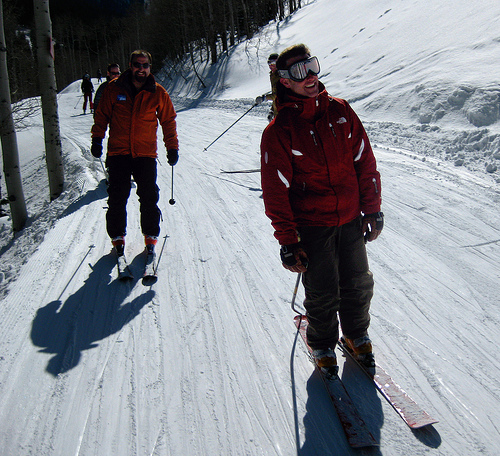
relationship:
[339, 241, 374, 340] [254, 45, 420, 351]
leg of person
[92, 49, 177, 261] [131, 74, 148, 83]
man with goatee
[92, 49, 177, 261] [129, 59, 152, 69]
man with sunglasses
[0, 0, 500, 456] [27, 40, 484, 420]
ground covering ground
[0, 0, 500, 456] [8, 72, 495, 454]
ground covering ground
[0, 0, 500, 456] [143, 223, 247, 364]
ground covering ground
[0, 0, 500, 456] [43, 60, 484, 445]
ground covering ground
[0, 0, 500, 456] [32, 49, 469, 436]
ground covering ground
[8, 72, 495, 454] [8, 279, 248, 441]
ground covered in snow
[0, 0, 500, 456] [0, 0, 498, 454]
ground covering ground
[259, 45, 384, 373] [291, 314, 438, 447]
man on skies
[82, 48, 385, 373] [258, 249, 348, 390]
men on skie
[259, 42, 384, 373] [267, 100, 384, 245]
man wearing red jacket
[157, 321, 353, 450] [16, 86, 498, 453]
marks in snow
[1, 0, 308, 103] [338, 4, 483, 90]
trees in snow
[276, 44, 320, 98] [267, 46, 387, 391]
head of person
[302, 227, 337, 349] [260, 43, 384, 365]
leg of person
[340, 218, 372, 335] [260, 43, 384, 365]
leg of person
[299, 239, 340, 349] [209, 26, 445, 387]
leg of person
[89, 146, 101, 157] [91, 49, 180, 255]
hand of man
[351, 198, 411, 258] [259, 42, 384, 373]
hand of man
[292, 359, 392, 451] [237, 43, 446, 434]
shadow of person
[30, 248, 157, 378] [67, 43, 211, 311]
person shadow of person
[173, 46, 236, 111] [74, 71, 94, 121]
shadow of person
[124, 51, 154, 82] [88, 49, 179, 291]
head of person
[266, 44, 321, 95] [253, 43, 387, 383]
head of person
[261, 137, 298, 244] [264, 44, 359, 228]
arm of person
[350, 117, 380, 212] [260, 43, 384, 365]
arm of person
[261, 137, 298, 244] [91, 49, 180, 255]
arm of man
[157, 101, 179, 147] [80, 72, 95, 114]
arm of person